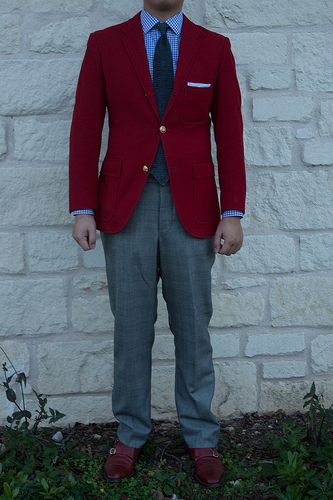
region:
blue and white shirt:
[133, 14, 183, 56]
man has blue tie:
[146, 29, 185, 180]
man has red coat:
[92, 31, 231, 230]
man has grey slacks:
[111, 198, 212, 440]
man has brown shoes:
[111, 438, 141, 486]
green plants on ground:
[151, 449, 326, 483]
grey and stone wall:
[231, 154, 317, 364]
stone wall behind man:
[255, 69, 322, 246]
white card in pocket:
[180, 70, 212, 108]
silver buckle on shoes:
[196, 439, 220, 464]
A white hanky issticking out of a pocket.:
[187, 82, 210, 87]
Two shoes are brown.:
[104, 438, 226, 485]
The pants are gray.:
[101, 175, 222, 451]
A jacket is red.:
[65, 9, 245, 237]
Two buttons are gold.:
[141, 124, 166, 173]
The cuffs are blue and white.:
[70, 209, 244, 214]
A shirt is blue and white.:
[138, 8, 184, 83]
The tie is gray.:
[151, 22, 172, 185]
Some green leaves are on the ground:
[0, 337, 332, 498]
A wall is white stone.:
[0, 10, 332, 426]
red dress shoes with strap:
[103, 445, 221, 487]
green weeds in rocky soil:
[0, 409, 332, 498]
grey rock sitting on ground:
[51, 430, 63, 441]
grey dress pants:
[101, 181, 217, 450]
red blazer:
[69, 15, 245, 239]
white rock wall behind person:
[0, 0, 332, 428]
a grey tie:
[148, 23, 176, 185]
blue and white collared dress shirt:
[140, 10, 181, 80]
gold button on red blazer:
[158, 125, 164, 132]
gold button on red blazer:
[141, 164, 145, 170]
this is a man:
[17, 14, 270, 344]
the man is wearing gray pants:
[101, 239, 232, 433]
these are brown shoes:
[84, 420, 236, 499]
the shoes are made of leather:
[99, 430, 145, 478]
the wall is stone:
[25, 262, 111, 402]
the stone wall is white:
[11, 237, 88, 364]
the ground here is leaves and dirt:
[31, 436, 77, 486]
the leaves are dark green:
[16, 427, 74, 495]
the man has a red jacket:
[75, 19, 270, 198]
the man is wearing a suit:
[67, 27, 232, 210]